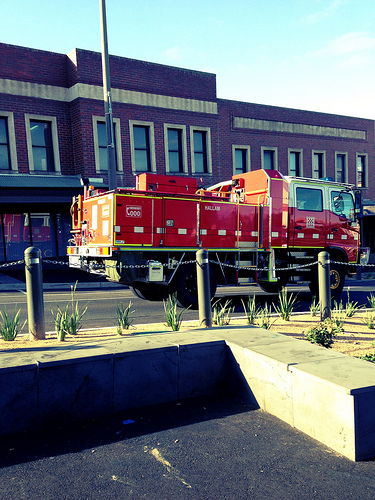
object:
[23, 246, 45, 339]
pole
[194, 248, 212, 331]
pole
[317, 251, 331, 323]
pole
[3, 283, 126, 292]
sidewalk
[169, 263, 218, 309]
wheels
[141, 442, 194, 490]
markings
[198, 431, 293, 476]
cement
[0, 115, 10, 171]
window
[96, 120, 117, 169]
window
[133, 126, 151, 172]
window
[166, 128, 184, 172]
window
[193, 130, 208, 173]
window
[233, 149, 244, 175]
window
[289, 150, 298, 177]
window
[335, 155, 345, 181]
window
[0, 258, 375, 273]
chain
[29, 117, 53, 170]
window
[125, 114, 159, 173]
window building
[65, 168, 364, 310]
truck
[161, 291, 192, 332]
plants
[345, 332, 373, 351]
dirt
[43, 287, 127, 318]
road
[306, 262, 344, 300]
front wheels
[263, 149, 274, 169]
window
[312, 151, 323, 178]
window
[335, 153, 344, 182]
window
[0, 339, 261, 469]
shadow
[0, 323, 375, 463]
ledge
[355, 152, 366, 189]
window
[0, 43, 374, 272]
building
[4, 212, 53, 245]
reflection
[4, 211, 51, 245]
window